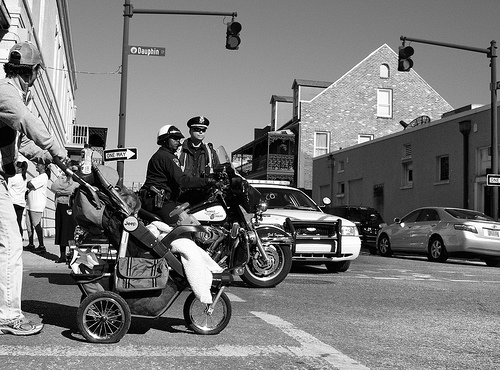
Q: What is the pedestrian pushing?
A: A stroller.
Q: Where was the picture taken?
A: On a street.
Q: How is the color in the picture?
A: Black and white.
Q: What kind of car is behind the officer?
A: A police car?.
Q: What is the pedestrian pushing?
A: A stroller.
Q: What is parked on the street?
A: Cars.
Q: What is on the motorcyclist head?
A: A helmet.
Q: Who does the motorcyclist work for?
A: Police.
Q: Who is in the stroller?
A: A baby.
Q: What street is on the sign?
A: Dauphin.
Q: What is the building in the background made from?
A: Brick.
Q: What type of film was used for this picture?
A: Black and white.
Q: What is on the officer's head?
A: Helmets.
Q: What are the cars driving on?
A: Street.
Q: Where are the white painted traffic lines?
A: On the pavement.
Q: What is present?
A: Cars.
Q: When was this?
A: Daytime.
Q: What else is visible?
A: A bike.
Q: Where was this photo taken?
A: On the street.